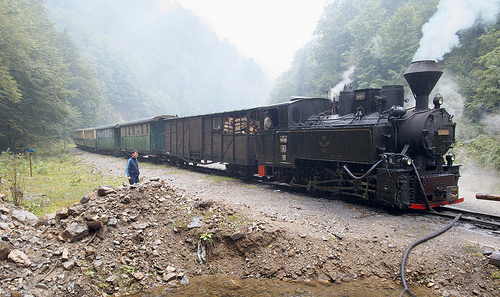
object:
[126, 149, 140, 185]
man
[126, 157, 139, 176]
jacket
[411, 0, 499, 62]
steam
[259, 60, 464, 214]
engine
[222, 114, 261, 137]
logs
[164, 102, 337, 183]
car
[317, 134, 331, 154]
logo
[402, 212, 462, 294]
hose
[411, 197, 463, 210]
bumper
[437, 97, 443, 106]
light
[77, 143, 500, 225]
tracks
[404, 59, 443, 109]
chimney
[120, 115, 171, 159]
car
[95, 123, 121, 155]
car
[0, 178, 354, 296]
dirt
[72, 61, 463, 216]
train